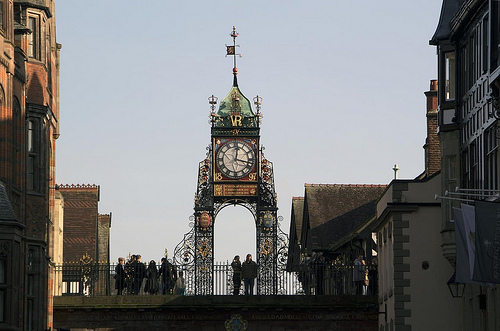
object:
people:
[229, 253, 243, 295]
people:
[241, 252, 258, 295]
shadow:
[2, 69, 52, 330]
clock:
[215, 139, 255, 179]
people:
[157, 257, 179, 294]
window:
[27, 16, 40, 59]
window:
[27, 116, 39, 189]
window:
[441, 54, 452, 99]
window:
[467, 136, 498, 189]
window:
[26, 244, 39, 323]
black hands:
[233, 146, 250, 165]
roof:
[298, 183, 393, 248]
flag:
[458, 203, 473, 282]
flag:
[470, 201, 498, 285]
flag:
[453, 211, 465, 282]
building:
[437, 0, 500, 330]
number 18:
[215, 172, 223, 180]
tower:
[166, 23, 304, 295]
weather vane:
[224, 26, 242, 73]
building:
[286, 183, 388, 295]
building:
[2, 0, 62, 330]